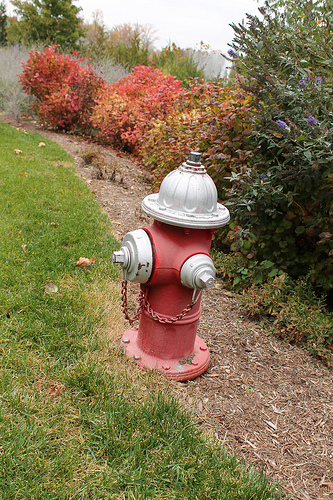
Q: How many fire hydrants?
A: One.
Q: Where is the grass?
A: In front of the hydrant.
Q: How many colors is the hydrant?
A: 2.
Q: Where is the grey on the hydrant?
A: On the caps.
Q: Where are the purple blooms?
A: Behind the hydrant.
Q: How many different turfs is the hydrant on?
A: 2.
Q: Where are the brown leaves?
A: On the ground.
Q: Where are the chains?
A: Connected to the hydrant.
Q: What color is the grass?
A: Green.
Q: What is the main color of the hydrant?
A: Red.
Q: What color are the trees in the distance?
A: Green.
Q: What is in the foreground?
A: Fire hydrant.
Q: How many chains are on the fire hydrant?
A: 2.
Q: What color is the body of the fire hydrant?
A: Red.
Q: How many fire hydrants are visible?
A: 1.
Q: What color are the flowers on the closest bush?
A: Purple.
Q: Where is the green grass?
A: Left side of picture.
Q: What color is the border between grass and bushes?
A: Brown.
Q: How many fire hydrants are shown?
A: 1.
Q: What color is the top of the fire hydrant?
A: White.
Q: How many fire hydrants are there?
A: 1.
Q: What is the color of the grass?
A: Green.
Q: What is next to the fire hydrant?
A: Flowers.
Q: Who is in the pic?
A: No one.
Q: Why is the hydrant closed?
A: There is no fire.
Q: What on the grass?
A: Leaves.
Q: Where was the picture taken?
A: Along the foliage.